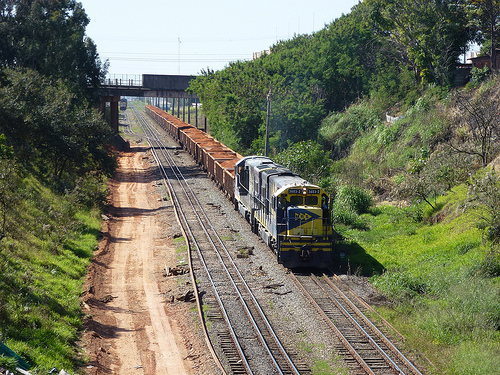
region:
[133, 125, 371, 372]
a train on a track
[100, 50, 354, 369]
a track with a train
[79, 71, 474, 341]
a long train on a track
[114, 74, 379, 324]
track with long trains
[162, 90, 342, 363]
two trains next to each other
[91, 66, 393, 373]
tracks surround by rocks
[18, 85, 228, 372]
a dirt road next to tracks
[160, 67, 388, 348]
a blue and yellow train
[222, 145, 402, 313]
blue and yellow train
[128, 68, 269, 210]
train cars filled up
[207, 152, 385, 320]
a train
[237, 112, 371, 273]
a train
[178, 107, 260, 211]
a train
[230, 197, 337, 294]
a train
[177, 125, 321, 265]
a train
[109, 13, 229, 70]
the sky is clear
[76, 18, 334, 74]
the sky is clear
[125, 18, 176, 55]
the sky is clear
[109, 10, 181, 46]
the sky is clear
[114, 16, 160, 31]
the sky is clear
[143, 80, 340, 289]
freight train on tracks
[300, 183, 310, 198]
front lights of a train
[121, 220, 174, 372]
dirt path by train tracks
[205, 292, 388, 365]
metal train tracks on ground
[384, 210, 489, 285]
green grass along side of hill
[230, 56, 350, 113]
green leaves of a tree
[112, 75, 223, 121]
bridge in the background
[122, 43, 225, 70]
electrical wires above ground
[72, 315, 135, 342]
shadow casted on the ground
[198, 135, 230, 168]
freight cars of a train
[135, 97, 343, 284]
train is hauling cargo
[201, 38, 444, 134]
trees have leaves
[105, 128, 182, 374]
dirt road on side of tracks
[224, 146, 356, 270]
engine is blue and yellow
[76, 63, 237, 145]
bridge over train tracks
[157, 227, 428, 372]
train tracks with gravel in between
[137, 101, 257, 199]
cargo mad of brown substance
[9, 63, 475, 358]
train tracks built at bottom of slope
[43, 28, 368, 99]
utility lines in background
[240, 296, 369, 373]
some grass is growing in gravel